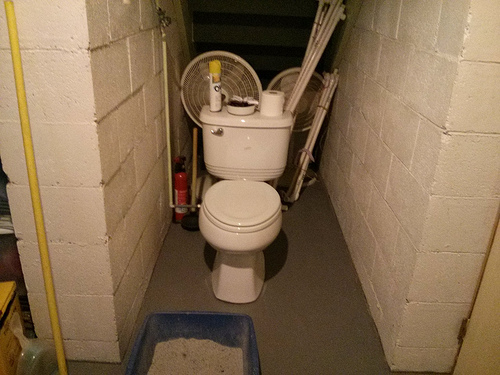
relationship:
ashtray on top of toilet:
[228, 102, 251, 116] [197, 93, 292, 308]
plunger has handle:
[187, 125, 210, 240] [188, 125, 202, 209]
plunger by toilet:
[187, 125, 210, 240] [197, 93, 292, 308]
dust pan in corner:
[3, 319, 54, 374] [16, 281, 79, 373]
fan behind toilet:
[184, 53, 271, 137] [197, 93, 292, 308]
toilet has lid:
[197, 93, 292, 308] [207, 181, 278, 226]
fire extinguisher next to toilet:
[171, 157, 194, 219] [197, 93, 292, 308]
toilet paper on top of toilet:
[257, 91, 290, 119] [197, 93, 292, 308]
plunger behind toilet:
[187, 125, 210, 240] [197, 93, 292, 308]